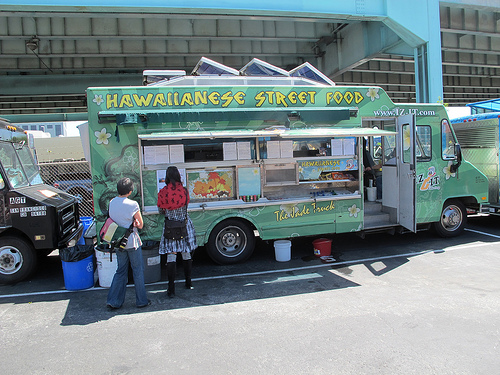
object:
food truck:
[80, 57, 495, 265]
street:
[1, 217, 499, 373]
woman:
[155, 166, 198, 298]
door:
[361, 115, 418, 234]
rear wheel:
[204, 217, 258, 266]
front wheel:
[434, 199, 466, 238]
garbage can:
[59, 245, 94, 290]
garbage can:
[92, 244, 124, 287]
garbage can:
[139, 246, 161, 283]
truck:
[0, 115, 83, 284]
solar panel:
[144, 69, 185, 85]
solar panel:
[191, 57, 238, 77]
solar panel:
[240, 58, 290, 77]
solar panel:
[288, 61, 336, 87]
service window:
[188, 168, 237, 204]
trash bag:
[60, 245, 94, 262]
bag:
[163, 211, 188, 239]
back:
[165, 253, 175, 298]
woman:
[95, 178, 152, 311]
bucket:
[274, 240, 292, 262]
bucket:
[312, 238, 333, 257]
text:
[103, 91, 364, 108]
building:
[32, 136, 90, 183]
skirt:
[158, 208, 198, 254]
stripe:
[0, 239, 497, 302]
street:
[254, 90, 318, 107]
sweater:
[157, 182, 189, 210]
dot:
[171, 198, 174, 203]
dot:
[171, 186, 176, 191]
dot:
[160, 194, 164, 198]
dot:
[179, 195, 183, 199]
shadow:
[61, 232, 497, 322]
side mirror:
[450, 143, 462, 172]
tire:
[0, 237, 37, 285]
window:
[183, 142, 223, 162]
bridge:
[0, 3, 500, 123]